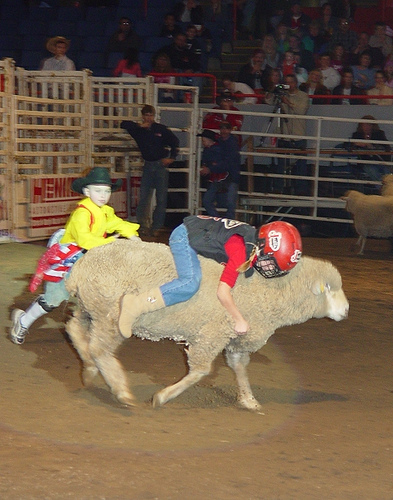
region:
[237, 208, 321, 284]
The person is wearing a helmet.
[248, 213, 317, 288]
The helmet is red.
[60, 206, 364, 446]
The person is riding a sheep.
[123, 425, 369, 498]
The ground is made of dirt.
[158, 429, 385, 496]
The ground is brown.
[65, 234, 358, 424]
The sheep is white.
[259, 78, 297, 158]
A person with a camera is in the background.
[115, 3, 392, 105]
People are in the stands.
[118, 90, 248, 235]
People are standing in the background.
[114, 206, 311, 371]
The person is wearing jeans.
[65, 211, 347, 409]
child riding on the back of a sheep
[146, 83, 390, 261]
white metal railing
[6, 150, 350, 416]
boy running behind sheep and rider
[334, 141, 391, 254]
sheep standing by railing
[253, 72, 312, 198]
man standing beside camera on tripod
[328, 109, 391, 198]
person sitting at table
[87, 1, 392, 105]
spectators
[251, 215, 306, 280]
boy wearing a red helmet with face protection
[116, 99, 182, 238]
man standing and leaning against railing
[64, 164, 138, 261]
boy wearing a black hat and a bright yellow shirt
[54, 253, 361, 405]
A beige woolly sheep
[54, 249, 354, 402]
The sheep is running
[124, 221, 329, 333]
The kid is wearing a red helmet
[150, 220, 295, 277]
The kids is wearing a black vest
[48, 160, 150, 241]
The boy has a black cowboy hat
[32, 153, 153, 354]
The boy is running behind the sheep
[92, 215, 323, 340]
The kid is on top of the sheep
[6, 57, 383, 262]
The tall metal bars are white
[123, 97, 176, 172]
The man has a black shirt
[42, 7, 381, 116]
People watching from the stadium seating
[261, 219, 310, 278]
a little boy wearing a red helmet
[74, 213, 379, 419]
a little boy riding a sheep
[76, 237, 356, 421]
white sheep running on dirt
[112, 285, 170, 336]
a boy wearing brown cowboy boots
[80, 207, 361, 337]
a boy holding on to sheep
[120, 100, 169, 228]
a man in blue next to gate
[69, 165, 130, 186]
a little boy wearing a black cowboy hat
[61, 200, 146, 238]
a little boy wearing a yellow shirt running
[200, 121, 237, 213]
a man in a black cowboy hat standing next to gate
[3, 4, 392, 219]
lots of people watching the radio outside the gate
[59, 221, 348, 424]
Small child on back of a sheep.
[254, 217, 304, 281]
Child wearing red helmet with face guard.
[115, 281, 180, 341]
Child wearing tan suede boots.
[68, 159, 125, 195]
Small boy wearing black hat.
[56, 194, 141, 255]
Small boy dressed in yellow shirt.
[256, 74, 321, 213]
Man standing on sideline taking pictures.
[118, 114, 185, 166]
Man standing on sideline dressed in long sleeve black shirt.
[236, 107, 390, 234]
Metal fence surrounding animal pen.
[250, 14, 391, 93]
People sitting up in bleachers.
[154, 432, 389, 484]
Dry brown dirt on arena floor.